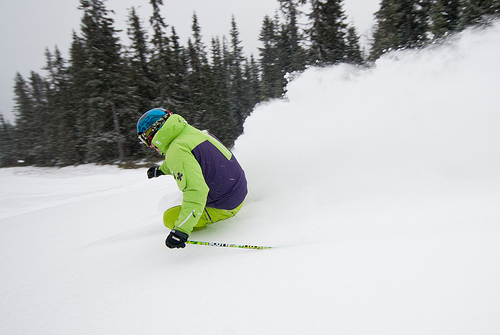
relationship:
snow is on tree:
[4, 17, 497, 332] [247, 51, 259, 111]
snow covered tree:
[4, 17, 497, 332] [9, 68, 46, 159]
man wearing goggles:
[137, 107, 248, 248] [131, 133, 157, 147]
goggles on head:
[131, 133, 157, 147] [138, 104, 179, 154]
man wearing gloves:
[137, 107, 248, 248] [161, 223, 215, 253]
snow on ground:
[293, 109, 481, 238] [22, 208, 490, 325]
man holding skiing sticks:
[135, 107, 248, 250] [184, 237, 285, 249]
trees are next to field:
[42, 18, 267, 157] [44, 139, 492, 330]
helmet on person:
[132, 106, 175, 147] [124, 101, 252, 253]